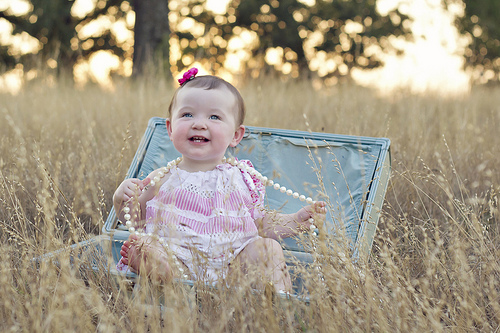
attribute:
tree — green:
[448, 4, 499, 91]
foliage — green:
[164, 2, 431, 63]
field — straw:
[15, 97, 498, 290]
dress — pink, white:
[150, 167, 262, 255]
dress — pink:
[119, 150, 326, 280]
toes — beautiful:
[92, 221, 201, 292]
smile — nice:
[179, 132, 212, 147]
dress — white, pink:
[140, 145, 294, 302]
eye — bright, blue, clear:
[180, 109, 193, 121]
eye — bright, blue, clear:
[205, 113, 221, 121]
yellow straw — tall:
[3, 160, 494, 331]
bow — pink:
[142, 63, 246, 104]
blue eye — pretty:
[208, 113, 219, 123]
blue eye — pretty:
[180, 110, 193, 120]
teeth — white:
[188, 135, 205, 142]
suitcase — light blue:
[18, 112, 403, 322]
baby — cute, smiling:
[106, 65, 327, 300]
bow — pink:
[178, 67, 197, 85]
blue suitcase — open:
[30, 104, 398, 312]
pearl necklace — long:
[112, 155, 319, 245]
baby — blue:
[38, 32, 320, 304]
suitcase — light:
[136, 126, 403, 268]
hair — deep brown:
[169, 75, 244, 125]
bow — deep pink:
[177, 67, 197, 86]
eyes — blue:
[176, 109, 221, 119]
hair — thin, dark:
[158, 74, 253, 138]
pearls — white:
[145, 156, 316, 204]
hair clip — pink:
[173, 57, 200, 91]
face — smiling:
[173, 77, 232, 155]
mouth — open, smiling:
[184, 128, 213, 148]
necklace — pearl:
[118, 146, 329, 276]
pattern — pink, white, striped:
[145, 189, 257, 238]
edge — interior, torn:
[245, 131, 383, 151]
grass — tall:
[3, 70, 498, 328]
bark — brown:
[135, 6, 169, 85]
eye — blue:
[208, 115, 224, 122]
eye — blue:
[179, 110, 193, 117]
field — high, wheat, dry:
[3, 80, 499, 330]